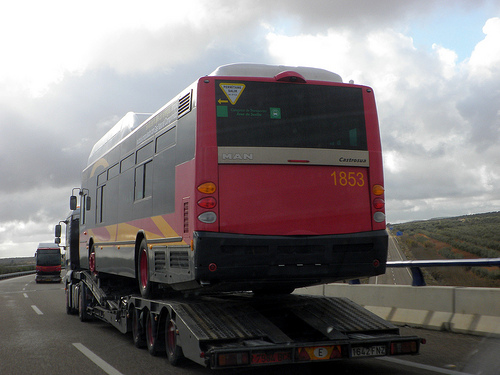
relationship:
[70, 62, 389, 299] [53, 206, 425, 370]
bus on top of truck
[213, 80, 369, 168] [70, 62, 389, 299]
window behind bus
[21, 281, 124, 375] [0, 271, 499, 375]
lines over highway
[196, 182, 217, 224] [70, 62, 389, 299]
tail light behind bus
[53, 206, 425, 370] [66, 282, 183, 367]
truck has wheels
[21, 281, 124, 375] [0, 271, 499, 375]
lines on highway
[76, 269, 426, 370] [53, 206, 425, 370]
flat bed behind truck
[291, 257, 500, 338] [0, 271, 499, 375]
gaurdrail on side of highway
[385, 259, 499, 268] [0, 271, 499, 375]
gaurdrail on side of highway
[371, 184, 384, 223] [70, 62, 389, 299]
break lights behind bus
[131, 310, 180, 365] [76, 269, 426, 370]
tires connected to flat bed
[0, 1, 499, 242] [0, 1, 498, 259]
clouds hovering in sky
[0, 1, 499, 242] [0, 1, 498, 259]
clouds over sky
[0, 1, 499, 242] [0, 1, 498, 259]
clouds under sky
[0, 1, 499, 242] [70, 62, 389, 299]
clouds above bus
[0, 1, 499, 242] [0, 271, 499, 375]
clouds above highway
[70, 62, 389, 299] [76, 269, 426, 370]
bus on top of flat bed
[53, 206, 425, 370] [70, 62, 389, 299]
truck moving bus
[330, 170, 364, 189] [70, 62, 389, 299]
number 1853 behind bus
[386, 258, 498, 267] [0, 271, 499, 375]
rail next to highway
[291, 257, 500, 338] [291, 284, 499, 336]
gaurdrail made of concrete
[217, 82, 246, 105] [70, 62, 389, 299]
sign behind bus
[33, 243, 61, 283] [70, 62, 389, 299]
truck in front of bus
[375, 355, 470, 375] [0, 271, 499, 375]
line on top of highway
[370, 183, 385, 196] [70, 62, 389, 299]
yellow light behind bus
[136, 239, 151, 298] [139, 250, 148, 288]
tire has red rim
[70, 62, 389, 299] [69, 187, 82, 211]
bus has side mirror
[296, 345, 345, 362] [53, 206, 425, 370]
yellow license plate behind truck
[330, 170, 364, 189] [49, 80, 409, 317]
number 1853 on a bus